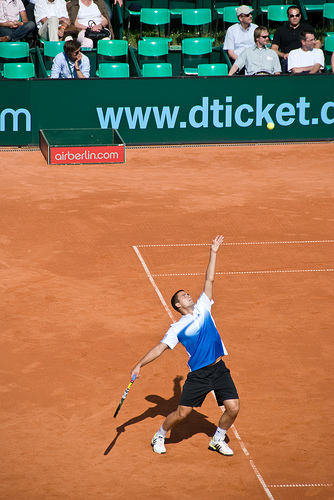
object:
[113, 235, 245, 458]
man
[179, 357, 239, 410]
shorts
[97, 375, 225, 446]
shadow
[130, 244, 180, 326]
line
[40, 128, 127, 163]
box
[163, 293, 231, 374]
shirt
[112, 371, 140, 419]
racket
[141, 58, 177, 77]
seat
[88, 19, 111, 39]
bag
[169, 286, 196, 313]
head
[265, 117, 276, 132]
ball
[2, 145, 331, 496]
court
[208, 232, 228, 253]
hand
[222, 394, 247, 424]
knee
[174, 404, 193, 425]
knee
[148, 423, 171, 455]
shoe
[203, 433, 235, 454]
shoe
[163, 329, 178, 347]
biciep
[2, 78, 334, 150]
advertisement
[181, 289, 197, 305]
face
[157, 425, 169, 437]
sock